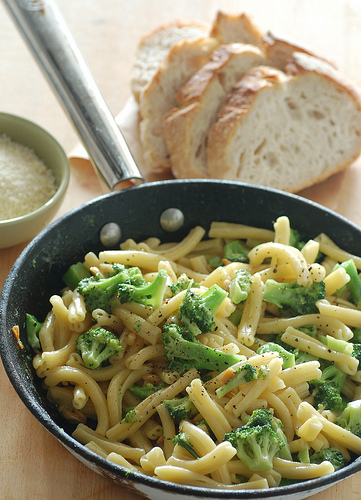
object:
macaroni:
[246, 241, 313, 288]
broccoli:
[222, 408, 282, 472]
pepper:
[105, 313, 118, 329]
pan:
[0, 2, 361, 499]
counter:
[2, 158, 360, 497]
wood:
[0, 362, 135, 500]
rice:
[1, 134, 57, 224]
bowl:
[0, 112, 70, 250]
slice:
[159, 30, 342, 178]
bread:
[207, 52, 360, 193]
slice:
[138, 12, 264, 173]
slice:
[131, 18, 202, 103]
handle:
[13, 2, 146, 190]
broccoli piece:
[76, 326, 121, 372]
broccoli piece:
[216, 365, 255, 403]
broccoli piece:
[264, 281, 324, 317]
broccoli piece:
[75, 268, 143, 314]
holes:
[233, 156, 250, 178]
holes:
[281, 96, 298, 123]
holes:
[264, 140, 290, 171]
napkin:
[67, 108, 144, 165]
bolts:
[99, 220, 122, 247]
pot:
[0, 178, 357, 492]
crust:
[291, 51, 357, 107]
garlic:
[8, 323, 24, 351]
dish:
[0, 176, 361, 500]